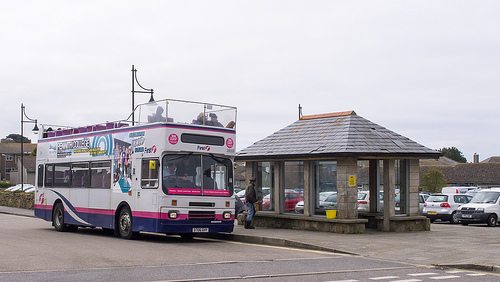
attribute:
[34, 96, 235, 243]
bus — double decker, stopped, double, leveled, driving, white, parked, passenger, two storied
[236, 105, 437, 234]
bus stop — enclosed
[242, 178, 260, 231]
man — standing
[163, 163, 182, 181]
driver — male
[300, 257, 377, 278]
pavement — gray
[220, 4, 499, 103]
sky — overcast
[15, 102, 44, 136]
light — metal, on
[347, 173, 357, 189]
sign — yellow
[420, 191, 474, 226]
car — parked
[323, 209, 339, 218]
bucket — yellow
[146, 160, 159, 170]
mirror — yellow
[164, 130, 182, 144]
sticker — pink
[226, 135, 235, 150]
sticker — pink